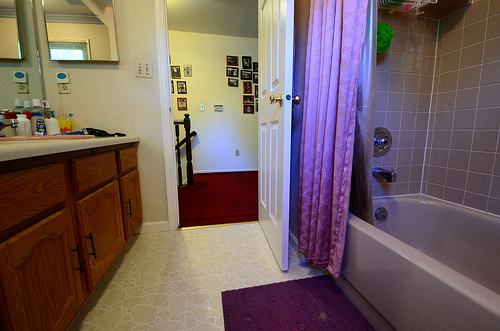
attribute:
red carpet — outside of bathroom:
[179, 168, 255, 217]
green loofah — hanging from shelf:
[376, 15, 394, 55]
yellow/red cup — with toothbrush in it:
[58, 114, 71, 132]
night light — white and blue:
[52, 67, 69, 86]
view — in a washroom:
[5, 6, 465, 329]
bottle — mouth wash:
[25, 91, 51, 142]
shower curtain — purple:
[292, 0, 367, 282]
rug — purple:
[220, 270, 377, 329]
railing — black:
[172, 111, 200, 191]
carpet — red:
[175, 170, 258, 230]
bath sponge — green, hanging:
[369, 21, 395, 62]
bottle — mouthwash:
[21, 90, 46, 133]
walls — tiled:
[399, 23, 484, 188]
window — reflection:
[16, 41, 91, 61]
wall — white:
[110, 2, 170, 222]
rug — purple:
[221, 281, 384, 329]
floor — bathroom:
[61, 216, 347, 329]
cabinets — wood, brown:
[4, 130, 147, 330]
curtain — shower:
[294, 0, 364, 281]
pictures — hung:
[217, 42, 269, 118]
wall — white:
[174, 28, 264, 180]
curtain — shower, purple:
[302, 7, 357, 277]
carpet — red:
[179, 162, 269, 230]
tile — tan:
[399, 35, 461, 155]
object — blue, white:
[49, 70, 69, 83]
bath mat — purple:
[218, 257, 348, 327]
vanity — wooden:
[10, 147, 143, 323]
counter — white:
[2, 96, 150, 155]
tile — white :
[101, 183, 289, 319]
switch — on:
[132, 56, 160, 82]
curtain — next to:
[304, 39, 350, 273]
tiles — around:
[437, 130, 477, 175]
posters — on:
[221, 52, 244, 98]